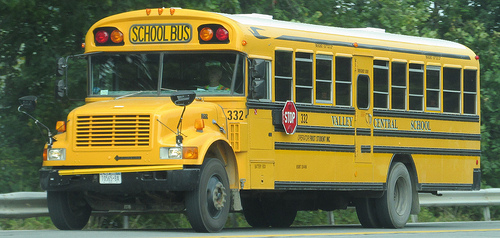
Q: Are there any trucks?
A: No, there are no trucks.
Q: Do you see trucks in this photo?
A: No, there are no trucks.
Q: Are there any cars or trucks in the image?
A: No, there are no trucks or cars.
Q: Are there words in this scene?
A: Yes, there are words.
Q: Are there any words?
A: Yes, there are words.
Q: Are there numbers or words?
A: Yes, there are words.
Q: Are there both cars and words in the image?
A: No, there are words but no cars.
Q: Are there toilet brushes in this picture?
A: No, there are no toilet brushes.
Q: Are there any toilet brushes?
A: No, there are no toilet brushes.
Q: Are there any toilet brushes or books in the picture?
A: No, there are no toilet brushes or books.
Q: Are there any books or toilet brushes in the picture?
A: No, there are no toilet brushes or books.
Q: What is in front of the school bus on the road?
A: The grill is in front of the school bus.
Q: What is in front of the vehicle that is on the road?
A: The grill is in front of the school bus.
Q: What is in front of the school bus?
A: The grill is in front of the school bus.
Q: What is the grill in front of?
A: The grill is in front of the school bus.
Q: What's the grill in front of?
A: The grill is in front of the school bus.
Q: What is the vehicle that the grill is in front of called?
A: The vehicle is a school bus.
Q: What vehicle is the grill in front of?
A: The grill is in front of the school bus.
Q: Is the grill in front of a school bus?
A: Yes, the grill is in front of a school bus.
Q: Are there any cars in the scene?
A: No, there are no cars.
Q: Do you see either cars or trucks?
A: No, there are no cars or trucks.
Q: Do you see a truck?
A: No, there are no trucks.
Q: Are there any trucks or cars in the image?
A: No, there are no trucks or cars.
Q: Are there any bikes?
A: No, there are no bikes.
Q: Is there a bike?
A: No, there are no bikes.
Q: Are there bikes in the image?
A: No, there are no bikes.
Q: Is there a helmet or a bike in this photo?
A: No, there are no bikes or helmets.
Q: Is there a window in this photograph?
A: Yes, there is a window.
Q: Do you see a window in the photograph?
A: Yes, there is a window.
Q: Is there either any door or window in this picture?
A: Yes, there is a window.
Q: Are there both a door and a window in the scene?
A: Yes, there are both a window and a door.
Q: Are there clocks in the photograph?
A: No, there are no clocks.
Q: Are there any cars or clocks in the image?
A: No, there are no clocks or cars.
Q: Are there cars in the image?
A: No, there are no cars.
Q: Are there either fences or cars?
A: No, there are no cars or fences.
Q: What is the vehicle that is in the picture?
A: The vehicle is a school bus.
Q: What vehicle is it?
A: The vehicle is a school bus.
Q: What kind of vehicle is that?
A: This is a school bus.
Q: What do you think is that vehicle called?
A: This is a school bus.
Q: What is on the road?
A: The school bus is on the road.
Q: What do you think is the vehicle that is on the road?
A: The vehicle is a school bus.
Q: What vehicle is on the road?
A: The vehicle is a school bus.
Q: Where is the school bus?
A: The school bus is on the road.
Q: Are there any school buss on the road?
A: Yes, there is a school bus on the road.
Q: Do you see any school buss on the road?
A: Yes, there is a school bus on the road.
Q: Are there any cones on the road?
A: No, there is a school bus on the road.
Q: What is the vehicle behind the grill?
A: The vehicle is a school bus.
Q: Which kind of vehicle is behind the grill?
A: The vehicle is a school bus.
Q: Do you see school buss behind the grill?
A: Yes, there is a school bus behind the grill.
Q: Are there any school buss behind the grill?
A: Yes, there is a school bus behind the grill.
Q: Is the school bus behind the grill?
A: Yes, the school bus is behind the grill.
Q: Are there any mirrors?
A: Yes, there is a mirror.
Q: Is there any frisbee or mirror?
A: Yes, there is a mirror.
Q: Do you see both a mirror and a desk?
A: No, there is a mirror but no desks.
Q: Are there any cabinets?
A: No, there are no cabinets.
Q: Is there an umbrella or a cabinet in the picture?
A: No, there are no cabinets or umbrellas.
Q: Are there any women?
A: No, there are no women.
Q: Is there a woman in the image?
A: No, there are no women.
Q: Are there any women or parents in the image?
A: No, there are no women or parents.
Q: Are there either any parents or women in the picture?
A: No, there are no women or parents.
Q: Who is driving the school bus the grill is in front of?
A: The man is driving the school bus.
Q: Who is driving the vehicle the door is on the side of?
A: The man is driving the school bus.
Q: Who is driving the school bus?
A: The man is driving the school bus.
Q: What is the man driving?
A: The man is driving the school bus.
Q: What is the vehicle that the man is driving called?
A: The vehicle is a school bus.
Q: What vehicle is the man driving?
A: The man is driving the school bus.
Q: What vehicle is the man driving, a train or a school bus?
A: The man is driving a school bus.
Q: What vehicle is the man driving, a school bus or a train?
A: The man is driving a school bus.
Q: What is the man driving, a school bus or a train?
A: The man is driving a school bus.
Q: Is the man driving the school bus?
A: Yes, the man is driving the school bus.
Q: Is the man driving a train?
A: No, the man is driving the school bus.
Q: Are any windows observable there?
A: Yes, there is a window.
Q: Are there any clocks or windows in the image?
A: Yes, there is a window.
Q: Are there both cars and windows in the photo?
A: No, there is a window but no cars.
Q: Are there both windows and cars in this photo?
A: No, there is a window but no cars.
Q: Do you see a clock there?
A: No, there are no clocks.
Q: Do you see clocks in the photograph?
A: No, there are no clocks.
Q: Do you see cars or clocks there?
A: No, there are no clocks or cars.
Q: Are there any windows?
A: Yes, there is a window.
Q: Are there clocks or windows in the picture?
A: Yes, there is a window.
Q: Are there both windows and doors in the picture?
A: Yes, there are both a window and a door.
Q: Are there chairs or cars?
A: No, there are no cars or chairs.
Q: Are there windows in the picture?
A: Yes, there is a window.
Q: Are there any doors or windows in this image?
A: Yes, there is a window.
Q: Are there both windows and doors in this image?
A: Yes, there are both a window and doors.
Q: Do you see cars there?
A: No, there are no cars.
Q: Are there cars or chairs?
A: No, there are no cars or chairs.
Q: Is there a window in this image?
A: Yes, there is a window.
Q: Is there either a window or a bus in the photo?
A: Yes, there is a window.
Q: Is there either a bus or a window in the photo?
A: Yes, there is a window.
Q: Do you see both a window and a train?
A: No, there is a window but no trains.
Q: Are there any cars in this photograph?
A: No, there are no cars.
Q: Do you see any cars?
A: No, there are no cars.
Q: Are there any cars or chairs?
A: No, there are no cars or chairs.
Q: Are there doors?
A: Yes, there is a door.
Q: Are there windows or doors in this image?
A: Yes, there is a door.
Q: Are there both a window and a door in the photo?
A: Yes, there are both a door and a window.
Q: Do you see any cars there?
A: No, there are no cars.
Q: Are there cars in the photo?
A: No, there are no cars.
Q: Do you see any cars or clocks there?
A: No, there are no cars or clocks.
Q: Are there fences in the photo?
A: No, there are no fences.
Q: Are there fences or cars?
A: No, there are no fences or cars.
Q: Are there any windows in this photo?
A: Yes, there is a window.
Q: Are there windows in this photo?
A: Yes, there is a window.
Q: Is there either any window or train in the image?
A: Yes, there is a window.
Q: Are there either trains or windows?
A: Yes, there is a window.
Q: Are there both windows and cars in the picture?
A: No, there is a window but no cars.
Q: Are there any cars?
A: No, there are no cars.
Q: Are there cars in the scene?
A: No, there are no cars.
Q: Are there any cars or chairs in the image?
A: No, there are no cars or chairs.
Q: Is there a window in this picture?
A: Yes, there is a window.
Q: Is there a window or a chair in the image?
A: Yes, there is a window.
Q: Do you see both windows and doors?
A: Yes, there are both a window and a door.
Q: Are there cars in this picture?
A: No, there are no cars.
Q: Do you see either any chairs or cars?
A: No, there are no cars or chairs.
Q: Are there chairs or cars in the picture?
A: No, there are no cars or chairs.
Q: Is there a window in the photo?
A: Yes, there is a window.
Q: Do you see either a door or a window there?
A: Yes, there is a window.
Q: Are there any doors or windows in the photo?
A: Yes, there is a window.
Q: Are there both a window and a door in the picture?
A: Yes, there are both a window and a door.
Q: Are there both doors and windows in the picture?
A: Yes, there are both a window and a door.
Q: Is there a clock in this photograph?
A: No, there are no clocks.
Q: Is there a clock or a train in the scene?
A: No, there are no clocks or trains.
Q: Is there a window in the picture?
A: Yes, there is a window.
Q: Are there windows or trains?
A: Yes, there is a window.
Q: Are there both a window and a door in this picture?
A: Yes, there are both a window and a door.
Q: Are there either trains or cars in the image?
A: No, there are no cars or trains.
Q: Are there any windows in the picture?
A: Yes, there is a window.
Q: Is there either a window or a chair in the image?
A: Yes, there is a window.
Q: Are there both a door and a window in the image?
A: Yes, there are both a window and a door.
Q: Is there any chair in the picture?
A: No, there are no chairs.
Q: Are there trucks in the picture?
A: No, there are no trucks.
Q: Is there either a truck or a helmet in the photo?
A: No, there are no trucks or helmets.